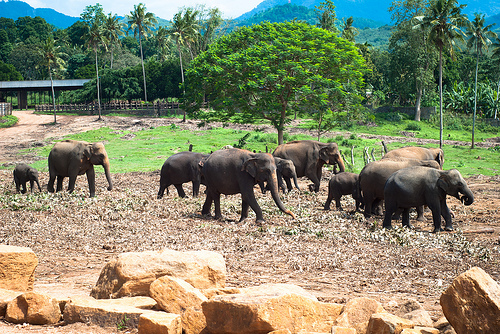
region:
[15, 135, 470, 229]
A herd of elephants walking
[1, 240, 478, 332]
Large rocks in the elephant enclosure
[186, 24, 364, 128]
Bright green leaves on a tree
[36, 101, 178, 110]
Wooden fence of an enclosure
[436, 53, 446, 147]
Thin trunk of a palm tree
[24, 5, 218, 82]
Green leaves of trees in the distance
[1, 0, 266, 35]
Mountains in the distance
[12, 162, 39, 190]
A baby elephant walking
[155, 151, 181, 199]
Back side of an elephant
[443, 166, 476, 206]
The head of an elephant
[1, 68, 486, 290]
a herd of elephants in a park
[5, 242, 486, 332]
rock in a preserve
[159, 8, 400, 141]
a tree in the preserve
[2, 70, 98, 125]
a shelter in the preserve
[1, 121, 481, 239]
ten elephants in the shot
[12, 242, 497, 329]
these rocks are brown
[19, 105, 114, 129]
a brown dirt area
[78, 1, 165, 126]
palm tries in the preserve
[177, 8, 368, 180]
PART OF A TREE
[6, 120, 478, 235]
A BUNCH OF ELEPHANTS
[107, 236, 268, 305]
ROCKS AND DRY GRASS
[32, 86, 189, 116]
PART OF A FENCE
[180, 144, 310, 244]
ELEPHANT ON DRY GRASS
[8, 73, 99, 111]
PART OF A BUILDING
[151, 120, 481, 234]
ELEPHANTS WALKING TO EACH OTHER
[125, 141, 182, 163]
PART OF A GREEN PASTURE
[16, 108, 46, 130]
PART OF A PATH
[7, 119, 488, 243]
A herd of elephant in captivity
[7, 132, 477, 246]
A herd of elephant in captivity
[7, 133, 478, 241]
A herd of elephant in captivity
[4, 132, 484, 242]
A herd of elephant in captivity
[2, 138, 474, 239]
A herd of elephant in captivity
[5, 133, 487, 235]
A herd of elephant in captivity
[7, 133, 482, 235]
A herd of elephant in captivity